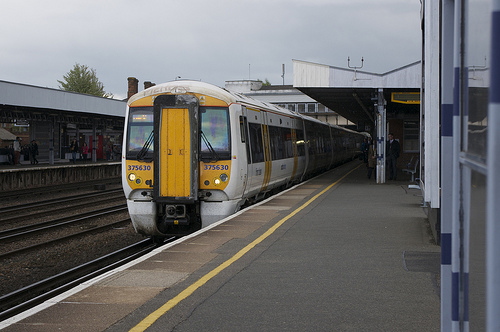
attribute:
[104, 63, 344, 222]
train —  foreground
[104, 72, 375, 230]
train — back view 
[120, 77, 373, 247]
passenger train — white, yellow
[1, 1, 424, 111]
sky — blue, cloudy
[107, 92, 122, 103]
cloud — white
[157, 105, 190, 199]
train door — yellow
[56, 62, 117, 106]
tree top — tall, green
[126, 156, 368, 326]
line — yellow, long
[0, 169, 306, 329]
line — white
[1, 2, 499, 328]
photo — outdoors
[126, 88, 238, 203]
front — yellow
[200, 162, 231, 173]
numbers — blue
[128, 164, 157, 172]
numbers — blue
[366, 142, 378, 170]
coat — brown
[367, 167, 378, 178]
pants — black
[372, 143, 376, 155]
shirt — white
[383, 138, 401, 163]
jacket — black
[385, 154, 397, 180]
pants — dark